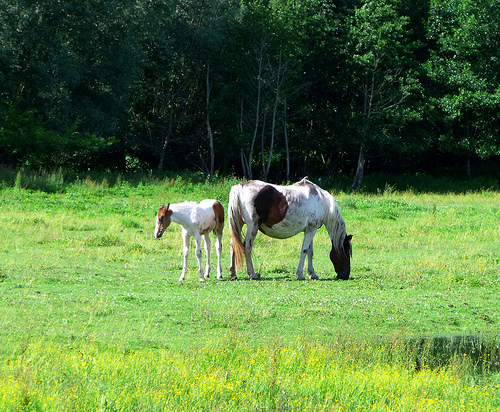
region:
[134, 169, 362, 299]
two horses in a field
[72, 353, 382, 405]
yellow flowering weeds in the grass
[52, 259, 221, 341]
field of green grass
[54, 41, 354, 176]
trees at the edge of the field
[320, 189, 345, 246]
white mane on the horse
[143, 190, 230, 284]
foal behind the larger horse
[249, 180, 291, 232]
brown spot on the horse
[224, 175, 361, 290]
horse grazing on the grass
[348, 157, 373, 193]
tree trunk at the edge of the field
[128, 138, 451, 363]
there are two horses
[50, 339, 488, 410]
there are yellow flowers in the grass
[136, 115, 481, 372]
two horses in a grassy field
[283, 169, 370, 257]
the horse's mane is white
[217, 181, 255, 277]
the long tail of a horse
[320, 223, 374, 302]
the horse's head is brown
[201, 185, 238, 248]
this horse also has a large brown spot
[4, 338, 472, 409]
yellow flowers are in the field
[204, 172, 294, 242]
the baby and mama both have a brown spot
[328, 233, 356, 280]
the mare's head is brown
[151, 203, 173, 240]
the baby has a white stripe on its head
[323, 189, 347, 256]
the mane of the horse has long white hair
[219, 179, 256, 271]
the horse's tail is white and brown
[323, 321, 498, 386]
water is in the field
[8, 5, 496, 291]
trees are behind the horses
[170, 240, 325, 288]
the horses' legs are white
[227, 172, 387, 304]
the horse is eating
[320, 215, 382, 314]
the horse is eating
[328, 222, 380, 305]
the horse is eating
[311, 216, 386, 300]
the horse is eating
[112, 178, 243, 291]
a small skinny horse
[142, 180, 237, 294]
a small skinny horse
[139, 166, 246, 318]
a small skinny horse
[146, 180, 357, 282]
Two horses in a field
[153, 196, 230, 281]
A baby colt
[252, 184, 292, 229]
A brown spot on a horse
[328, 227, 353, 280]
A horse's brown head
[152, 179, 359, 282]
A baby horse by its mother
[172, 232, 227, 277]
The colt's thin legs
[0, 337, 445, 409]
Small yellow flowers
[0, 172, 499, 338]
A field of green grass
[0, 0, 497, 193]
Trees surrounding the field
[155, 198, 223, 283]
white and brown baby horse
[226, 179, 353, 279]
adult horse grazing on grass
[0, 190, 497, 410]
field of green grass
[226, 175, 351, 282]
white horse with spot on body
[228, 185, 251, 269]
long flowing horse tail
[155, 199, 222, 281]
horse with brown head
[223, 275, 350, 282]
shadow of horse on grass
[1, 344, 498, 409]
overgrown weeds with yellow flowers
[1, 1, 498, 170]
green leaves on branches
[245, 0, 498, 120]
light reflection on leaves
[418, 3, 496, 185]
a tree in the woods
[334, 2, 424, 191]
a tree in the woods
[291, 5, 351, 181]
a tree in the woods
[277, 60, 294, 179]
a tree in the woods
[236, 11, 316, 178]
a tree in the woods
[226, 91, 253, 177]
a tree in the woods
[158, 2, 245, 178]
a tree in the woods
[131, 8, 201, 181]
a tree in the woods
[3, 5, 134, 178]
a tree in the woods